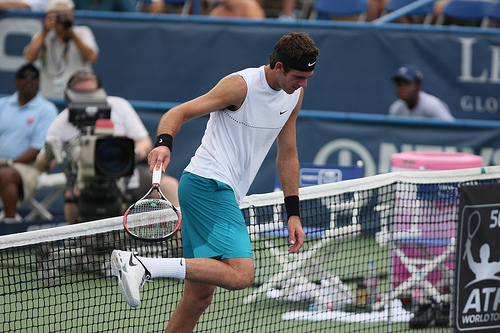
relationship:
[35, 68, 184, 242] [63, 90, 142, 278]
man operating a camera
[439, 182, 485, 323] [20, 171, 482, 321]
sign on a net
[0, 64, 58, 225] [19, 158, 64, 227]
man sitting in a chair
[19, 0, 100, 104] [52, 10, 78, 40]
man holding a camera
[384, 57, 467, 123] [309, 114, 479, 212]
man behind a barrier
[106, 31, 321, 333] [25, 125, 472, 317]
man on a court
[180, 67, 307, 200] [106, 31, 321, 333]
tshirt worn by man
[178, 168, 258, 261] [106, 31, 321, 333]
shorts of man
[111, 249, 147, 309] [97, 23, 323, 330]
shoe of man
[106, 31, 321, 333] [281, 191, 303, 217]
man wearing wristband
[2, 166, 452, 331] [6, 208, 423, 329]
net dividing court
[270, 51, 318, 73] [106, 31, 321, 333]
band on man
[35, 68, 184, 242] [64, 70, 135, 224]
man operating camera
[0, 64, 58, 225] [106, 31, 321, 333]
man watching man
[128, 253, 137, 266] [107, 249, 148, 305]
check on shoe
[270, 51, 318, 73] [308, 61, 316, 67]
band with check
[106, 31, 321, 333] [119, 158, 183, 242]
man swings racket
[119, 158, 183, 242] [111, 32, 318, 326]
racket held by man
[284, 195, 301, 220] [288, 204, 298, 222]
band on wrist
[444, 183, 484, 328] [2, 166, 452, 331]
flag by net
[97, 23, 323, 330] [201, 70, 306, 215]
man wearing white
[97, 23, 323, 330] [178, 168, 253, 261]
man wearing shorts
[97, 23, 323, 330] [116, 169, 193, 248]
man holding racquet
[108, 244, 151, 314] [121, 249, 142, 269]
shoe with check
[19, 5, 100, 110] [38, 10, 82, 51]
man holding camera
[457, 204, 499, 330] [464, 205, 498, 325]
sign with lettering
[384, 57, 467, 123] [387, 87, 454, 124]
man in white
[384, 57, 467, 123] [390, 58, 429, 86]
man wearing cap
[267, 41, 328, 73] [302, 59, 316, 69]
band with check